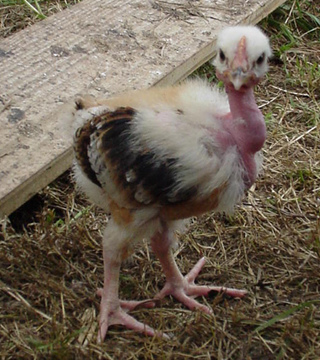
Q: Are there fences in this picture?
A: No, there are no fences.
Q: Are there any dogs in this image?
A: No, there are no dogs.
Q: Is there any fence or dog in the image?
A: No, there are no dogs or fences.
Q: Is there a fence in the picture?
A: No, there are no fences.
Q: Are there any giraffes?
A: No, there are no giraffes.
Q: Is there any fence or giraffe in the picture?
A: No, there are no giraffes or fences.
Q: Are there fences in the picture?
A: No, there are no fences.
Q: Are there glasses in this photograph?
A: No, there are no glasses.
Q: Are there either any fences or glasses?
A: No, there are no glasses or fences.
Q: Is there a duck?
A: No, there are no ducks.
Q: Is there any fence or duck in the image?
A: No, there are no ducks or fences.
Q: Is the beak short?
A: Yes, the beak is short.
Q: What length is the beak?
A: The beak is short.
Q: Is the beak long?
A: No, the beak is short.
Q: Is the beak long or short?
A: The beak is short.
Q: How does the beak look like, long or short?
A: The beak is short.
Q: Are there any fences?
A: No, there are no fences.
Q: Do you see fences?
A: No, there are no fences.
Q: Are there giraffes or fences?
A: No, there are no fences or giraffes.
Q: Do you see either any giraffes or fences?
A: No, there are no fences or giraffes.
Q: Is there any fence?
A: No, there are no fences.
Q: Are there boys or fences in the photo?
A: No, there are no fences or boys.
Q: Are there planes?
A: No, there are no planes.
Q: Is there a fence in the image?
A: No, there are no fences.